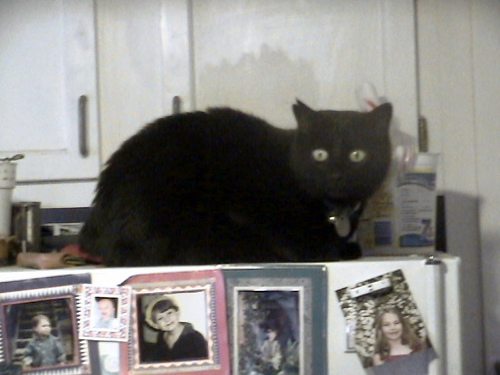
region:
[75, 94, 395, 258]
Black cat looking at the camera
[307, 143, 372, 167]
Eyes of black cat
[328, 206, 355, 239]
Tag on collar of cat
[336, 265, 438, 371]
Picture of a girl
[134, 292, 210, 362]
Picture of a child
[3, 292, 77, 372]
Picture of a child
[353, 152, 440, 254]
White bucket behind cat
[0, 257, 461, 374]
White refrigerator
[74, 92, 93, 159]
Handle of cabinet door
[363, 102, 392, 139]
Left ear of black cat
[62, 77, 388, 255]
the cat is black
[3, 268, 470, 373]
pictures of a family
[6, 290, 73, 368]
a picture of a baby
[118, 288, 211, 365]
a picture of a child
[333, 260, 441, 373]
a picture of a young lady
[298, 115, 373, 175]
the cat has green eyes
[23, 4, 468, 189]
white cabinets above the cap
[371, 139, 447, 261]
an item by the cat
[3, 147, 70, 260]
obejcts behind the cat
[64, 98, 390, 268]
the cat is black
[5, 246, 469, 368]
a refrigerator under the cat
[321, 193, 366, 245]
a collar under the cat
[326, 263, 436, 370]
a photograph on the fridge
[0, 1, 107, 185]
a cupboard behind the cat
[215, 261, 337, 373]
a picture in a green frame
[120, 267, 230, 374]
a photo in a pink frame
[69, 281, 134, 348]
a photo in a white frame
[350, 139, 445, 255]
a box behind the cat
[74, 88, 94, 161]
a handle on the cupboard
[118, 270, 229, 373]
Red mat under a picture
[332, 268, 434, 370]
Girl's picture on a refrigerator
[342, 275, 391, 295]
Magnet on a girl's picture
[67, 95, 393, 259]
Black cat on top of a refrigerator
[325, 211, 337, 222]
Bell on a cat's collar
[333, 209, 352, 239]
Tags on a cat's collar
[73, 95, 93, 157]
Handle on a cabinet door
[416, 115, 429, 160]
Hinge on a cabinet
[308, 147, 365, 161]
Eyes on a black cat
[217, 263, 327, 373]
Frame on a refrigerator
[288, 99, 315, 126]
Cat has black ear.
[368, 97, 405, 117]
Cat has black ear.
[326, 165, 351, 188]
Cat has black nose.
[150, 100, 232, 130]
Cat has black back.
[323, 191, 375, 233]
Cat is wearing collar on neck.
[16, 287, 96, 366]
Framed picture on fridge.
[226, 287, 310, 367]
Framed picture on fridge.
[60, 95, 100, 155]
Dark handle attached to cupboard.